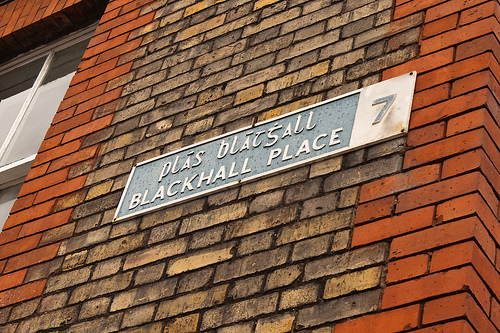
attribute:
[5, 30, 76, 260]
lines — white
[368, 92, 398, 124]
seven — blue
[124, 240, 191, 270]
brick — yellow, black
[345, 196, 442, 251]
brick — red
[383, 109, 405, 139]
spot — black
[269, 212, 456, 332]
bricks — orange, tan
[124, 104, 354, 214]
writing — white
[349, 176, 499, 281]
bricks — red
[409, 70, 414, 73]
bolt — tiny, black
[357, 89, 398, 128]
number — grey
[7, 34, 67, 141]
window frame — white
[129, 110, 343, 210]
lettering — white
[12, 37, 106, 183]
pane — glass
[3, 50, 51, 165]
pane — glass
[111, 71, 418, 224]
sign — black, street, blue, white, address, grey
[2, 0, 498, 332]
wall — brick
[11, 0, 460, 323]
bricks — red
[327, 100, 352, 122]
specks — grey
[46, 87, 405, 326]
building — old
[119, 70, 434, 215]
sign — grey, white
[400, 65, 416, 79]
screw — round, black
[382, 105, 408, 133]
mark — black